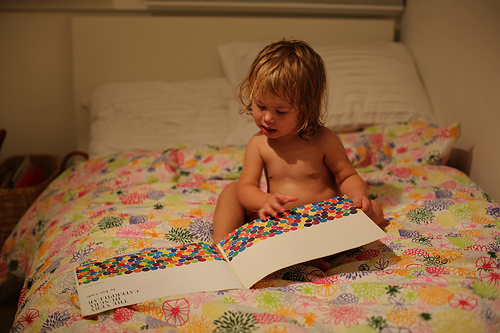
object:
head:
[252, 41, 322, 139]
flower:
[117, 224, 143, 241]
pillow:
[82, 80, 229, 160]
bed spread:
[0, 121, 499, 332]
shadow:
[445, 144, 475, 176]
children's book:
[74, 192, 386, 318]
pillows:
[216, 36, 436, 146]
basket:
[0, 150, 62, 241]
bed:
[62, 15, 500, 332]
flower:
[162, 297, 192, 325]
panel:
[73, 13, 399, 152]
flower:
[215, 311, 255, 333]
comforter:
[9, 35, 500, 321]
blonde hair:
[237, 36, 330, 141]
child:
[205, 31, 389, 257]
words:
[82, 281, 140, 313]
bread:
[14, 120, 491, 328]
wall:
[386, 2, 498, 206]